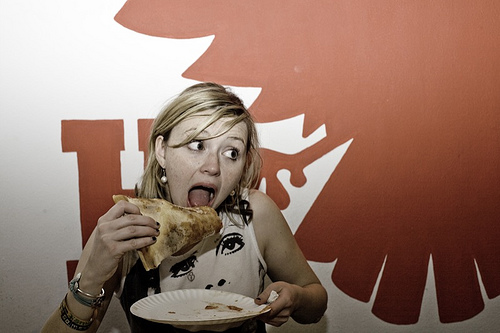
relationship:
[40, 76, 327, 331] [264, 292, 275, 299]
lady holding a slice of pizza napkin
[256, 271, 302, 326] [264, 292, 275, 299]
hand holding pizza and plate napkin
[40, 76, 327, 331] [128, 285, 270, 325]
lady holding paper plate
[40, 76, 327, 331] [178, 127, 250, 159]
lady with eyes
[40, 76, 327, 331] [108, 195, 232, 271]
lady eats pizza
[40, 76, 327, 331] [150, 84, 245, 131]
lady has blonde hair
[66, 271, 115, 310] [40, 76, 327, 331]
bracelets on lady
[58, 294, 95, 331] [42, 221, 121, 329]
bracelets on arm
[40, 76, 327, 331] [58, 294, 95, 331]
lady wears bracelets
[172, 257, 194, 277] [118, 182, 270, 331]
eye on shirt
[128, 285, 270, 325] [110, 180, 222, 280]
paper plate under pizza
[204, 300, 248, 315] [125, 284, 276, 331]
sauce on plate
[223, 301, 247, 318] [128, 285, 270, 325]
sauce on paper plate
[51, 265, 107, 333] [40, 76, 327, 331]
bracelets on lady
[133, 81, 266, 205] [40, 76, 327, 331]
hair on lady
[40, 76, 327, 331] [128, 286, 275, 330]
lady holding paper plate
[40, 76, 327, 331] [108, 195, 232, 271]
lady eating pizza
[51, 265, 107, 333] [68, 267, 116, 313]
bracelets on womans wrist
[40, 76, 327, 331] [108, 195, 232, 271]
lady holding pizza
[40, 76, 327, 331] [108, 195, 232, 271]
lady standing up while eating pizza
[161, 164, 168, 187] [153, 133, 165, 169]
earring is on ear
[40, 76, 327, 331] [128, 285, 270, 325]
lady is holding paper plate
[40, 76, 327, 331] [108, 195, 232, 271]
lady is holding pizza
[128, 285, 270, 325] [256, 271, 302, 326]
paper plate in hand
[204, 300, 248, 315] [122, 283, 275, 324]
sauce on a paper plate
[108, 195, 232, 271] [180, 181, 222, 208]
pizza about to enter mouth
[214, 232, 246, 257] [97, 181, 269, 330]
eye on shirt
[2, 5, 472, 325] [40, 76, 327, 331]
wall behind lady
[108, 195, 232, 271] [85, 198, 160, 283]
pizza in hand